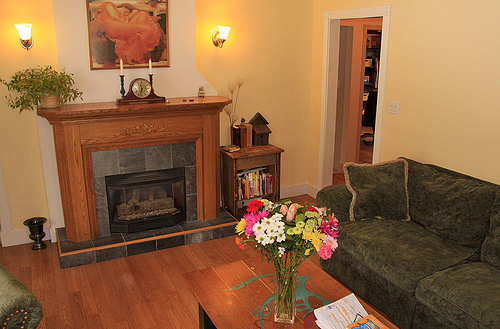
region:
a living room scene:
[12, 13, 454, 320]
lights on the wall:
[4, 4, 237, 62]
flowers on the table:
[215, 190, 334, 326]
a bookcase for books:
[230, 117, 295, 213]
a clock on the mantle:
[103, 58, 177, 108]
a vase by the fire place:
[18, 208, 55, 258]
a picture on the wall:
[75, 2, 179, 74]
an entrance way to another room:
[327, 21, 393, 164]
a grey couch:
[320, 141, 496, 323]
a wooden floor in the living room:
[63, 251, 273, 326]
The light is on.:
[208, 20, 238, 45]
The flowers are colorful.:
[228, 189, 342, 264]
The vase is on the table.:
[229, 191, 335, 323]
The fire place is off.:
[43, 84, 226, 256]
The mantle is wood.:
[43, 94, 240, 126]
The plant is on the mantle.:
[9, 66, 79, 113]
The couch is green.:
[313, 152, 497, 321]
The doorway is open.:
[309, 6, 396, 209]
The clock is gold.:
[110, 64, 170, 101]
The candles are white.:
[110, 54, 162, 71]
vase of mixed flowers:
[232, 188, 322, 321]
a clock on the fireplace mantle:
[115, 52, 177, 104]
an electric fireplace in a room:
[34, 95, 246, 261]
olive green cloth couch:
[309, 150, 498, 324]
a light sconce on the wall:
[10, 17, 41, 55]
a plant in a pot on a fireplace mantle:
[5, 55, 76, 116]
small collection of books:
[234, 169, 284, 199]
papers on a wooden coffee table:
[308, 288, 373, 328]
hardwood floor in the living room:
[66, 270, 165, 323]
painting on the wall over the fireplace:
[82, 1, 191, 82]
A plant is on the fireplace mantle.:
[1, 64, 232, 253]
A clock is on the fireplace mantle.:
[30, 44, 236, 251]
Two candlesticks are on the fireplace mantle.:
[33, 43, 243, 258]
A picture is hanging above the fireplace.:
[31, 0, 230, 250]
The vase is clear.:
[226, 188, 351, 328]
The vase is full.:
[226, 190, 339, 327]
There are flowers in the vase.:
[228, 185, 350, 327]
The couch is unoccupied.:
[312, 143, 499, 326]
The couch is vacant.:
[313, 150, 499, 327]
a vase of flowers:
[235, 184, 336, 323]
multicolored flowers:
[238, 189, 338, 264]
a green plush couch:
[315, 135, 497, 322]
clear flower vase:
[265, 273, 301, 323]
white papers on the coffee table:
[309, 291, 369, 327]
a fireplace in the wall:
[37, 95, 242, 262]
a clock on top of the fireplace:
[122, 75, 164, 105]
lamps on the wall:
[8, 22, 230, 50]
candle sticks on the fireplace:
[115, 50, 165, 102]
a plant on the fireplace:
[8, 60, 80, 115]